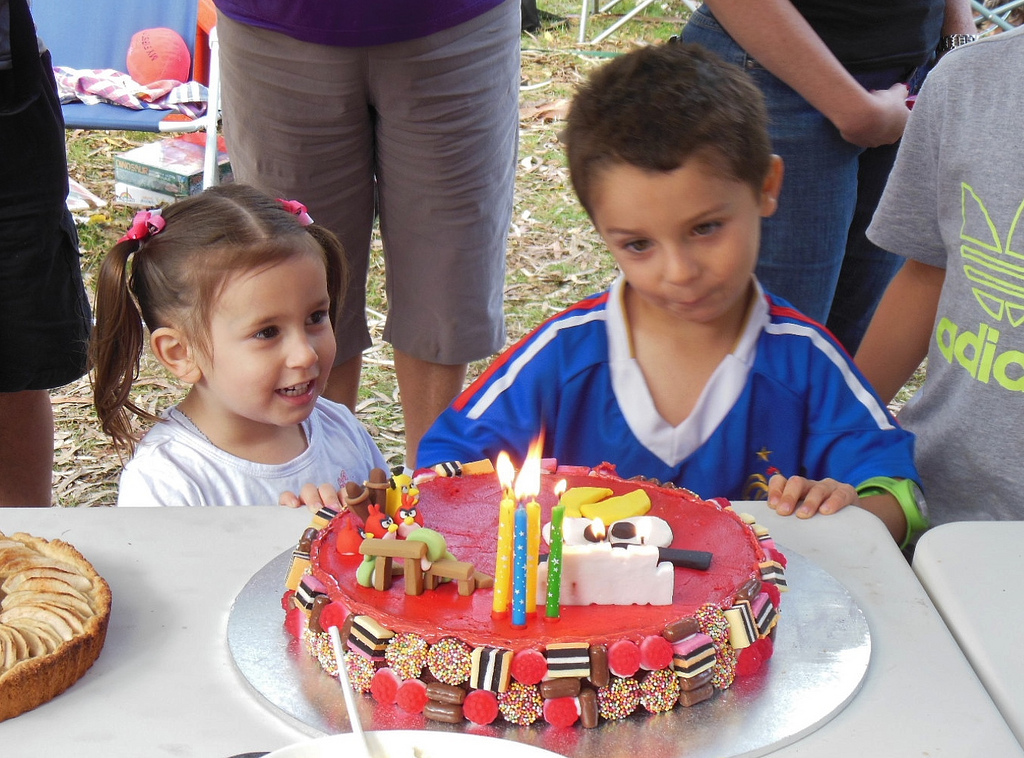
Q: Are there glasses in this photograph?
A: No, there are no glasses.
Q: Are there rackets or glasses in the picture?
A: No, there are no glasses or rackets.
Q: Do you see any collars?
A: Yes, there is a collar.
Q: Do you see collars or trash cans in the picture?
A: Yes, there is a collar.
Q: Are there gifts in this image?
A: No, there are no gifts.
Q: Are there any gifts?
A: No, there are no gifts.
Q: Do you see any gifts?
A: No, there are no gifts.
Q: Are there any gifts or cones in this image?
A: No, there are no gifts or cones.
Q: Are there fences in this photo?
A: No, there are no fences.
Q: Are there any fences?
A: No, there are no fences.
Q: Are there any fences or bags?
A: No, there are no fences or bags.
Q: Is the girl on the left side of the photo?
A: Yes, the girl is on the left of the image.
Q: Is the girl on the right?
A: No, the girl is on the left of the image.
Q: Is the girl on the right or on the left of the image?
A: The girl is on the left of the image.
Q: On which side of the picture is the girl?
A: The girl is on the left of the image.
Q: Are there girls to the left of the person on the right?
A: Yes, there is a girl to the left of the person.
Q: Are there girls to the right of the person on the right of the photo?
A: No, the girl is to the left of the person.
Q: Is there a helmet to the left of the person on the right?
A: No, there is a girl to the left of the person.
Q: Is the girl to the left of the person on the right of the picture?
A: Yes, the girl is to the left of the person.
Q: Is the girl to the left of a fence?
A: No, the girl is to the left of the person.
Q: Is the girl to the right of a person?
A: No, the girl is to the left of a person.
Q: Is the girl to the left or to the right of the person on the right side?
A: The girl is to the left of the person.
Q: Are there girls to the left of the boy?
A: Yes, there is a girl to the left of the boy.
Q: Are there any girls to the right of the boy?
A: No, the girl is to the left of the boy.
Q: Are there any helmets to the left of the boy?
A: No, there is a girl to the left of the boy.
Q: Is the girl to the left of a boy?
A: Yes, the girl is to the left of a boy.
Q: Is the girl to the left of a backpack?
A: No, the girl is to the left of a boy.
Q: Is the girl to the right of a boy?
A: No, the girl is to the left of a boy.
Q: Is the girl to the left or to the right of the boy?
A: The girl is to the left of the boy.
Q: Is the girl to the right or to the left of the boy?
A: The girl is to the left of the boy.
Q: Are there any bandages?
A: No, there are no bandages.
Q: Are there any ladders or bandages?
A: No, there are no bandages or ladders.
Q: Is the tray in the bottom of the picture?
A: Yes, the tray is in the bottom of the image.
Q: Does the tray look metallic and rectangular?
A: No, the tray is metallic but round.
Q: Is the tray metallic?
A: Yes, the tray is metallic.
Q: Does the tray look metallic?
A: Yes, the tray is metallic.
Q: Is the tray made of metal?
A: Yes, the tray is made of metal.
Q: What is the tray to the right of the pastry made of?
A: The tray is made of metal.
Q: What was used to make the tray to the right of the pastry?
A: The tray is made of metal.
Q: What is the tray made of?
A: The tray is made of metal.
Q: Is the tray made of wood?
A: No, the tray is made of metal.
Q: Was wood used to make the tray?
A: No, the tray is made of metal.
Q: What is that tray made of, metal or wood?
A: The tray is made of metal.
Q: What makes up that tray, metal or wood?
A: The tray is made of metal.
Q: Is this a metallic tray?
A: Yes, this is a metallic tray.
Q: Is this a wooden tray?
A: No, this is a metallic tray.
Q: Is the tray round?
A: Yes, the tray is round.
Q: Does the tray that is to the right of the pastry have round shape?
A: Yes, the tray is round.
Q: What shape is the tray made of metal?
A: The tray is round.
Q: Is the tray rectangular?
A: No, the tray is round.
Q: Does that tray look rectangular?
A: No, the tray is round.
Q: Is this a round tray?
A: Yes, this is a round tray.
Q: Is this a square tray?
A: No, this is a round tray.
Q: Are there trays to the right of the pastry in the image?
A: Yes, there is a tray to the right of the pastry.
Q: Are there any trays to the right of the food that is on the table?
A: Yes, there is a tray to the right of the pastry.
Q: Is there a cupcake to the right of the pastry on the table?
A: No, there is a tray to the right of the pastry.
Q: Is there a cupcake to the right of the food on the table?
A: No, there is a tray to the right of the pastry.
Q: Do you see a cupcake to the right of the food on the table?
A: No, there is a tray to the right of the pastry.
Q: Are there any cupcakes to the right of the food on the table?
A: No, there is a tray to the right of the pastry.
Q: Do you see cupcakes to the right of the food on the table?
A: No, there is a tray to the right of the pastry.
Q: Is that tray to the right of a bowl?
A: No, the tray is to the right of the pastry.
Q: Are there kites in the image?
A: No, there are no kites.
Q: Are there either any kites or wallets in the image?
A: No, there are no kites or wallets.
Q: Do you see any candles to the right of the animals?
A: Yes, there is a candle to the right of the animals.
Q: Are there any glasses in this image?
A: No, there are no glasses.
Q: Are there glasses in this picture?
A: No, there are no glasses.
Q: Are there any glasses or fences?
A: No, there are no glasses or fences.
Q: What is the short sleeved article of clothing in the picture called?
A: The clothing item is a shirt.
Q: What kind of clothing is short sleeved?
A: The clothing is a shirt.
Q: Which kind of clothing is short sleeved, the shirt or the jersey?
A: The shirt is short sleeved.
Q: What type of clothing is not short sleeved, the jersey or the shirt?
A: The jersey is not short sleeved.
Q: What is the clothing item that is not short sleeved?
A: The clothing item is a jersey.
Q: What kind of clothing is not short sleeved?
A: The clothing is a jersey.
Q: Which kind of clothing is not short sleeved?
A: The clothing is a jersey.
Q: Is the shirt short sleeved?
A: Yes, the shirt is short sleeved.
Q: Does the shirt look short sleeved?
A: Yes, the shirt is short sleeved.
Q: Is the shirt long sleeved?
A: No, the shirt is short sleeved.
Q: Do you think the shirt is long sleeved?
A: No, the shirt is short sleeved.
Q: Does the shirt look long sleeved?
A: No, the shirt is short sleeved.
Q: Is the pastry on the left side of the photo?
A: Yes, the pastry is on the left of the image.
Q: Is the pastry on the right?
A: No, the pastry is on the left of the image.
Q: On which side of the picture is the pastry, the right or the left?
A: The pastry is on the left of the image.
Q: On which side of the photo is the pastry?
A: The pastry is on the left of the image.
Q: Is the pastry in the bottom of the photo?
A: Yes, the pastry is in the bottom of the image.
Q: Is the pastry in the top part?
A: No, the pastry is in the bottom of the image.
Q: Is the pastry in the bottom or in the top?
A: The pastry is in the bottom of the image.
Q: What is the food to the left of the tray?
A: The food is a pastry.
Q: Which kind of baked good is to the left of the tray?
A: The food is a pastry.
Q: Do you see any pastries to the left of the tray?
A: Yes, there is a pastry to the left of the tray.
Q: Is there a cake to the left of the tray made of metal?
A: No, there is a pastry to the left of the tray.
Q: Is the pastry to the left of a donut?
A: No, the pastry is to the left of the tray.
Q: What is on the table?
A: The pastry is on the table.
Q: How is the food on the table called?
A: The food is a pastry.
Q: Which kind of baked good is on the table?
A: The food is a pastry.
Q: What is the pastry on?
A: The pastry is on the table.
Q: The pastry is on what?
A: The pastry is on the table.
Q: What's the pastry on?
A: The pastry is on the table.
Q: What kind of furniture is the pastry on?
A: The pastry is on the table.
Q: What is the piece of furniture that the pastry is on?
A: The piece of furniture is a table.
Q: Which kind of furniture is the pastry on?
A: The pastry is on the table.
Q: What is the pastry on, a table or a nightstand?
A: The pastry is on a table.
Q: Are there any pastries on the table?
A: Yes, there is a pastry on the table.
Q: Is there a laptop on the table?
A: No, there is a pastry on the table.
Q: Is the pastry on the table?
A: Yes, the pastry is on the table.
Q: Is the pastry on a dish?
A: No, the pastry is on the table.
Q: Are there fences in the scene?
A: No, there are no fences.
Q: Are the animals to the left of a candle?
A: Yes, the animals are to the left of a candle.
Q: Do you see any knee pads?
A: No, there are no knee pads.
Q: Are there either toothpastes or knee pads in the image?
A: No, there are no knee pads or toothpastes.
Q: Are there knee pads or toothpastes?
A: No, there are no knee pads or toothpastes.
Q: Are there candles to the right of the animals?
A: Yes, there is a candle to the right of the animals.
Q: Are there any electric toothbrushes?
A: No, there are no electric toothbrushes.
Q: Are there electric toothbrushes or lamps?
A: No, there are no electric toothbrushes or lamps.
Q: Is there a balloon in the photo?
A: Yes, there is a balloon.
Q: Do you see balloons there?
A: Yes, there is a balloon.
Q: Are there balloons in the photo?
A: Yes, there is a balloon.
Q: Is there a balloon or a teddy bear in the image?
A: Yes, there is a balloon.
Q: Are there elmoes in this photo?
A: No, there are no elmoes.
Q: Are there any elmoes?
A: No, there are no elmoes.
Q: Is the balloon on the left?
A: Yes, the balloon is on the left of the image.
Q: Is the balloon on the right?
A: No, the balloon is on the left of the image.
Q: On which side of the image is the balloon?
A: The balloon is on the left of the image.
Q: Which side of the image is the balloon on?
A: The balloon is on the left of the image.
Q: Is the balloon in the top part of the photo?
A: Yes, the balloon is in the top of the image.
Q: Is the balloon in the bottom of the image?
A: No, the balloon is in the top of the image.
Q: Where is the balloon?
A: The balloon is on the floor.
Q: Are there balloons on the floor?
A: Yes, there is a balloon on the floor.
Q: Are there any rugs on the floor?
A: No, there is a balloon on the floor.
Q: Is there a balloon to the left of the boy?
A: Yes, there is a balloon to the left of the boy.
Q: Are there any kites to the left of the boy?
A: No, there is a balloon to the left of the boy.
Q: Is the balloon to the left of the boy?
A: Yes, the balloon is to the left of the boy.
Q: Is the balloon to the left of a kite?
A: No, the balloon is to the left of the boy.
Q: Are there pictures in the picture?
A: No, there are no pictures.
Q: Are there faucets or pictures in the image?
A: No, there are no pictures or faucets.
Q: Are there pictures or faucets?
A: No, there are no pictures or faucets.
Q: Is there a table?
A: Yes, there is a table.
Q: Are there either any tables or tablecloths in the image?
A: Yes, there is a table.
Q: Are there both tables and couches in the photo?
A: No, there is a table but no couches.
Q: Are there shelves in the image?
A: No, there are no shelves.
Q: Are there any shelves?
A: No, there are no shelves.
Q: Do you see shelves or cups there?
A: No, there are no shelves or cups.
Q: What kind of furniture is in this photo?
A: The furniture is a table.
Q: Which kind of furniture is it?
A: The piece of furniture is a table.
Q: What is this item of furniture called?
A: This is a table.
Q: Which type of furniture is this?
A: This is a table.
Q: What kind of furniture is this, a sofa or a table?
A: This is a table.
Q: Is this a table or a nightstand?
A: This is a table.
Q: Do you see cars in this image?
A: No, there are no cars.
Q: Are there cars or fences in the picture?
A: No, there are no cars or fences.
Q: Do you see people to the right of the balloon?
A: No, the person is to the left of the balloon.